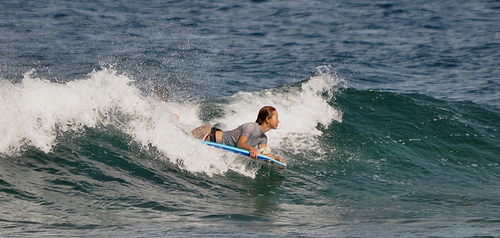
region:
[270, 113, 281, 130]
the man is light skinned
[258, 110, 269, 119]
this is the hair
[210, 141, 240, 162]
this is a surfboard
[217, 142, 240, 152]
the surfboard is blue in color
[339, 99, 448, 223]
this is a water body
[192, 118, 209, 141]
the short is brown in color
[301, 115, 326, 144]
part of a splash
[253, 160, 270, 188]
edge of a board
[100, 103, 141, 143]
pasrt of a splashj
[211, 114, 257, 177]
erdge f a board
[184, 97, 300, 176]
the woman is ridng a body board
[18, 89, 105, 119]
the water is white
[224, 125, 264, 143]
the shirt is gray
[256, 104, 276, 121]
her hair is wet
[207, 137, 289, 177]
the board is blue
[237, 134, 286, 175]
the woman is holding onto the board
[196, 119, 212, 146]
her shorts are tan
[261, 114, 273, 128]
the woman has an ear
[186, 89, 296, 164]
woman surfing in the ocean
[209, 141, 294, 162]
blue boogie board under woman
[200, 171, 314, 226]
light reflecting off water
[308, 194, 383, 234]
dark green water of the ocean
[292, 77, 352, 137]
white water on crest of wave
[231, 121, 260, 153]
gray wet suit on woman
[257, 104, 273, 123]
wet hair of woman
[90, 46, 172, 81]
water spraying up in air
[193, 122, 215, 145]
tan pants on woman surfing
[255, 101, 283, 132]
woman with short brown hair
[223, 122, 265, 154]
wet gray short sleeved T shirt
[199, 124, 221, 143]
black wet bikini bottom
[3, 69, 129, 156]
section of white sea spray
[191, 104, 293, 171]
one woman on blue surfboard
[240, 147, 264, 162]
right hand gripping surfboard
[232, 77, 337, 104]
white capped ocean wave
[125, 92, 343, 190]
one surfer lying on surfboard